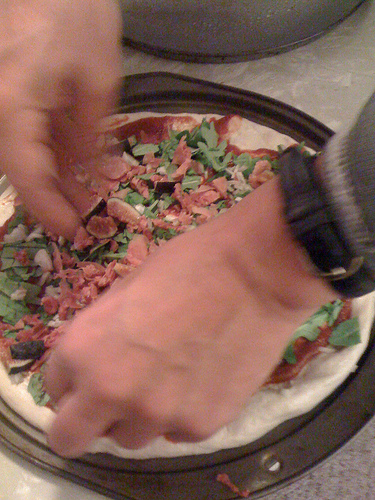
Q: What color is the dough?
A: White.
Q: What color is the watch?
A: Black.